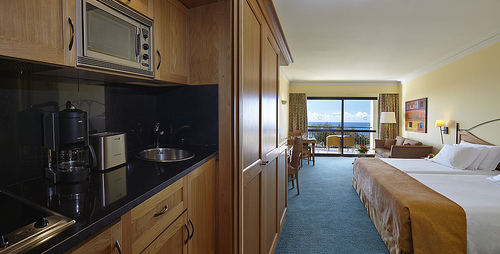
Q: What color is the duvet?
A: Brown.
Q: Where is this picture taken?
A: Hotel room.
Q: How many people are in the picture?
A: Zero.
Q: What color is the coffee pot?
A: Black.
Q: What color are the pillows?
A: White.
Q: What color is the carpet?
A: Blue.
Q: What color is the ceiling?
A: White.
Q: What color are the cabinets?
A: Brown.